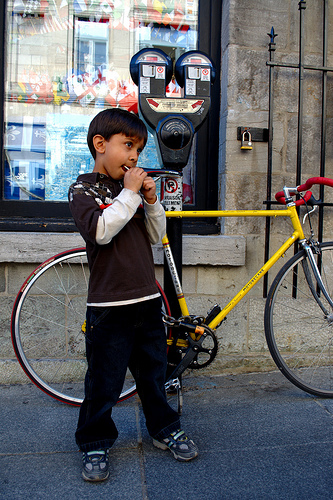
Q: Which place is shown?
A: It is a sidewalk.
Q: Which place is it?
A: It is a sidewalk.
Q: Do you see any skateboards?
A: No, there are no skateboards.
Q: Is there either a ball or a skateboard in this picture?
A: No, there are no skateboards or balls.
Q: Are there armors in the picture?
A: No, there are no armors.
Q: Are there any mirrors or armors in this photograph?
A: No, there are no armors or mirrors.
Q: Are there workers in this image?
A: No, there are no workers.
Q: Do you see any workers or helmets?
A: No, there are no workers or helmets.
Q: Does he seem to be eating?
A: Yes, the boy is eating.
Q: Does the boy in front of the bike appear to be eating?
A: Yes, the boy is eating.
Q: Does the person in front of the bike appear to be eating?
A: Yes, the boy is eating.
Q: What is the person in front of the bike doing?
A: The boy is eating.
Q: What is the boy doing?
A: The boy is eating.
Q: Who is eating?
A: The boy is eating.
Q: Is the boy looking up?
A: No, the boy is eating.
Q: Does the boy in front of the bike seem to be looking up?
A: No, the boy is eating.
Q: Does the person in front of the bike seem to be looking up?
A: No, the boy is eating.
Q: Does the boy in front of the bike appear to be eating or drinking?
A: The boy is eating.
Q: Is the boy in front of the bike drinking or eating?
A: The boy is eating.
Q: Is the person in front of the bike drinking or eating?
A: The boy is eating.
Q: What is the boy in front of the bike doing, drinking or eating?
A: The boy is eating.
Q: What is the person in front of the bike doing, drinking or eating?
A: The boy is eating.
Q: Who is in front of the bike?
A: The boy is in front of the bike.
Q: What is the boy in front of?
A: The boy is in front of the bike.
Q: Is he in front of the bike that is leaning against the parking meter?
A: Yes, the boy is in front of the bike.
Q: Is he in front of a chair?
A: No, the boy is in front of the bike.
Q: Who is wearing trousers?
A: The boy is wearing trousers.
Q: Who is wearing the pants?
A: The boy is wearing trousers.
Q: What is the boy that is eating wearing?
A: The boy is wearing pants.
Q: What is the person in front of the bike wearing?
A: The boy is wearing pants.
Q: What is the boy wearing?
A: The boy is wearing pants.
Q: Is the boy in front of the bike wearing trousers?
A: Yes, the boy is wearing trousers.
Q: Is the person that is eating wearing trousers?
A: Yes, the boy is wearing trousers.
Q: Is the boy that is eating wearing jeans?
A: No, the boy is wearing trousers.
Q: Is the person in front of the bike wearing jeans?
A: No, the boy is wearing trousers.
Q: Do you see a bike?
A: Yes, there is a bike.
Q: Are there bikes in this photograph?
A: Yes, there is a bike.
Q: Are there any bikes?
A: Yes, there is a bike.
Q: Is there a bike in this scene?
A: Yes, there is a bike.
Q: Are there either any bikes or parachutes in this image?
A: Yes, there is a bike.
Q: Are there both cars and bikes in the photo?
A: No, there is a bike but no cars.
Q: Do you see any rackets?
A: No, there are no rackets.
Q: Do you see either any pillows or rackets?
A: No, there are no rackets or pillows.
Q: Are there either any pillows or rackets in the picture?
A: No, there are no rackets or pillows.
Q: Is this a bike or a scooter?
A: This is a bike.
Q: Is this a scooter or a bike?
A: This is a bike.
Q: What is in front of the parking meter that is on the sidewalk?
A: The bike is in front of the meter.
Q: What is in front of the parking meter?
A: The bike is in front of the meter.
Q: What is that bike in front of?
A: The bike is in front of the parking meter.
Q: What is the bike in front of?
A: The bike is in front of the parking meter.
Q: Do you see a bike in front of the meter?
A: Yes, there is a bike in front of the meter.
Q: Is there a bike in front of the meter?
A: Yes, there is a bike in front of the meter.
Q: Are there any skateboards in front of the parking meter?
A: No, there is a bike in front of the parking meter.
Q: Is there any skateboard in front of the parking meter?
A: No, there is a bike in front of the parking meter.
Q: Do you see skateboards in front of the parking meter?
A: No, there is a bike in front of the parking meter.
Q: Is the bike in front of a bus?
A: No, the bike is in front of the parking meter.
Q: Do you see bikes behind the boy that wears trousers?
A: Yes, there is a bike behind the boy.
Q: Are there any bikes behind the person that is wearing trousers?
A: Yes, there is a bike behind the boy.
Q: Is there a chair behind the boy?
A: No, there is a bike behind the boy.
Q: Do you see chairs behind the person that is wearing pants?
A: No, there is a bike behind the boy.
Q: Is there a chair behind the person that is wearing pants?
A: No, there is a bike behind the boy.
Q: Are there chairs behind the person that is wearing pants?
A: No, there is a bike behind the boy.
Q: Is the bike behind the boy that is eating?
A: Yes, the bike is behind the boy.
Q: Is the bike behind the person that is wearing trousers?
A: Yes, the bike is behind the boy.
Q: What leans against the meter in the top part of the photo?
A: The bike leans against the meter.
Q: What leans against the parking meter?
A: The bike leans against the meter.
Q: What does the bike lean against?
A: The bike leans against the meter.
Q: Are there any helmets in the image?
A: No, there are no helmets.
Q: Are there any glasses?
A: No, there are no glasses.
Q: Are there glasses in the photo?
A: No, there are no glasses.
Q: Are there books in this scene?
A: No, there are no books.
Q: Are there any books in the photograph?
A: No, there are no books.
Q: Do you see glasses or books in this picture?
A: No, there are no books or glasses.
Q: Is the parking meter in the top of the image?
A: Yes, the parking meter is in the top of the image.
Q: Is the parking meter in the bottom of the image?
A: No, the parking meter is in the top of the image.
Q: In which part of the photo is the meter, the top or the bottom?
A: The meter is in the top of the image.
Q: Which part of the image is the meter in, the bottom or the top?
A: The meter is in the top of the image.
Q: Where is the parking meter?
A: The parking meter is on the sidewalk.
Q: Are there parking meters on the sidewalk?
A: Yes, there is a parking meter on the sidewalk.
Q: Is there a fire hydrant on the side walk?
A: No, there is a parking meter on the side walk.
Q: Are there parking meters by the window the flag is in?
A: Yes, there is a parking meter by the window.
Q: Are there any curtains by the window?
A: No, there is a parking meter by the window.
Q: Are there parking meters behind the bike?
A: Yes, there is a parking meter behind the bike.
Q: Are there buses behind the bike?
A: No, there is a parking meter behind the bike.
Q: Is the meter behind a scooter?
A: No, the meter is behind the bike.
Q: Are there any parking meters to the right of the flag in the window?
A: Yes, there is a parking meter to the right of the flag.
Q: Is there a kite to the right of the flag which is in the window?
A: No, there is a parking meter to the right of the flag.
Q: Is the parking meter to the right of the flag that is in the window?
A: Yes, the parking meter is to the right of the flag.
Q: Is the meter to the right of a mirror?
A: No, the meter is to the right of the flag.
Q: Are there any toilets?
A: No, there are no toilets.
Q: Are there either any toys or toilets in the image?
A: No, there are no toilets or toys.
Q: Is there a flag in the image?
A: Yes, there is a flag.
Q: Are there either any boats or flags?
A: Yes, there is a flag.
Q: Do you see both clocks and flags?
A: No, there is a flag but no clocks.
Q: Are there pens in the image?
A: No, there are no pens.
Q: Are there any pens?
A: No, there are no pens.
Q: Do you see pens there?
A: No, there are no pens.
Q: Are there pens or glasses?
A: No, there are no pens or glasses.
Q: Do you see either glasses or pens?
A: No, there are no pens or glasses.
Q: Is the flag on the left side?
A: Yes, the flag is on the left of the image.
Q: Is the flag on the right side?
A: No, the flag is on the left of the image.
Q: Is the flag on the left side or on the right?
A: The flag is on the left of the image.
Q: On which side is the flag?
A: The flag is on the left of the image.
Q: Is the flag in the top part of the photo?
A: Yes, the flag is in the top of the image.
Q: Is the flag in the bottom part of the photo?
A: No, the flag is in the top of the image.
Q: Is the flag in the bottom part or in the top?
A: The flag is in the top of the image.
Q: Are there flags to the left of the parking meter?
A: Yes, there is a flag to the left of the parking meter.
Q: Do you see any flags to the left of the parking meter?
A: Yes, there is a flag to the left of the parking meter.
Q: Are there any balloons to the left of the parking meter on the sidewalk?
A: No, there is a flag to the left of the parking meter.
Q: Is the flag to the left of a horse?
A: No, the flag is to the left of the parking meter.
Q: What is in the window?
A: The flag is in the window.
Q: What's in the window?
A: The flag is in the window.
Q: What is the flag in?
A: The flag is in the window.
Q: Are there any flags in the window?
A: Yes, there is a flag in the window.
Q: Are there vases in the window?
A: No, there is a flag in the window.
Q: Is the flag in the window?
A: Yes, the flag is in the window.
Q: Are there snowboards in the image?
A: No, there are no snowboards.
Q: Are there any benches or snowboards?
A: No, there are no snowboards or benches.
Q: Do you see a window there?
A: Yes, there is a window.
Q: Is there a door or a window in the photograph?
A: Yes, there is a window.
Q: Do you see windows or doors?
A: Yes, there is a window.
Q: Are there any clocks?
A: No, there are no clocks.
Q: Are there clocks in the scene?
A: No, there are no clocks.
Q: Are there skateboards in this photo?
A: No, there are no skateboards.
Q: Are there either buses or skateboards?
A: No, there are no skateboards or buses.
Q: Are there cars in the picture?
A: No, there are no cars.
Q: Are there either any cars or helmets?
A: No, there are no cars or helmets.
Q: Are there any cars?
A: No, there are no cars.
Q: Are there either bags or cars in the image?
A: No, there are no cars or bags.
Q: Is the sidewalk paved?
A: Yes, the sidewalk is paved.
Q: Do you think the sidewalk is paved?
A: Yes, the sidewalk is paved.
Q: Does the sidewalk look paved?
A: Yes, the sidewalk is paved.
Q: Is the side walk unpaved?
A: No, the side walk is paved.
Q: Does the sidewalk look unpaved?
A: No, the sidewalk is paved.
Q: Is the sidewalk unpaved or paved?
A: The sidewalk is paved.